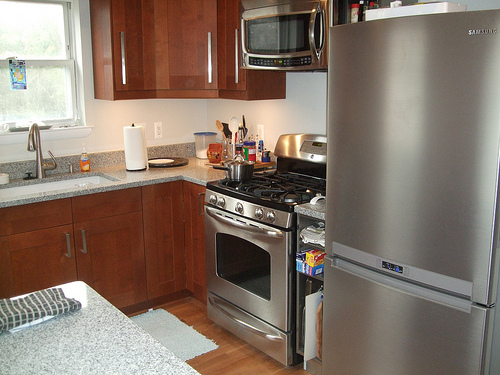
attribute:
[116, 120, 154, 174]
paper towels — roll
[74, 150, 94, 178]
bottle — hand soap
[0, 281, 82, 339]
towel — black, white, checkered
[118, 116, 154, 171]
paper towels — roll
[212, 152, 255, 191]
pot — silver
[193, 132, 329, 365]
stove — stainless steel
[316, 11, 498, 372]
refrigerator — stainless steel, silver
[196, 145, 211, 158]
substance — white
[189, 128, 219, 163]
container — plastic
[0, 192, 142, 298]
cabinets — wooden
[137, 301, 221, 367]
rug — white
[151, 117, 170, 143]
wall outlet — white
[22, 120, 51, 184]
sink faucet — grey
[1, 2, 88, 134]
kitchen window — pictured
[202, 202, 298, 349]
oven — pictured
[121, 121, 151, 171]
towel roll — paper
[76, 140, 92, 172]
hand soap — liquid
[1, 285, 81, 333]
towel — folded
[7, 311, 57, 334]
towel — folded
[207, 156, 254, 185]
pot — silver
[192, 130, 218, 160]
canister — plastic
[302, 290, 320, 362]
cutting board — large, white, plastic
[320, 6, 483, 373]
refrigerator — silver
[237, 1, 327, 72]
microwave — over-the-range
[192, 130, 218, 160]
container — blue, white, plastic